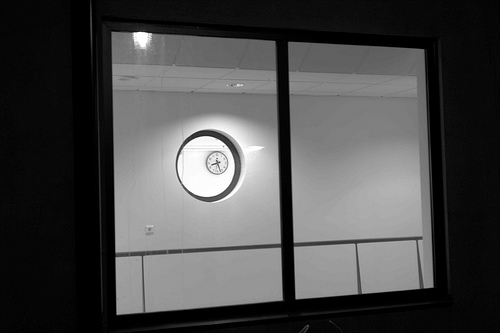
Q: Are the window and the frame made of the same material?
A: No, the window is made of glass and the frame is made of metal.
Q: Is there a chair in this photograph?
A: No, there are no chairs.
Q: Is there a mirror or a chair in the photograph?
A: No, there are no chairs or mirrors.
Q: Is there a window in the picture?
A: Yes, there is a window.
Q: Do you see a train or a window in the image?
A: Yes, there is a window.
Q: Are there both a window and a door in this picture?
A: No, there is a window but no doors.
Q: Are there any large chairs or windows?
A: Yes, there is a large window.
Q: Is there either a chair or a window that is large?
A: Yes, the window is large.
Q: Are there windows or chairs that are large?
A: Yes, the window is large.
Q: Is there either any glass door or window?
A: Yes, there is a glass window.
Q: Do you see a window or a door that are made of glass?
A: Yes, the window is made of glass.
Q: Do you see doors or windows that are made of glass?
A: Yes, the window is made of glass.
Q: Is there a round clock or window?
A: Yes, there is a round window.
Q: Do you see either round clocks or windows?
A: Yes, there is a round window.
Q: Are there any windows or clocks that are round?
A: Yes, the window is round.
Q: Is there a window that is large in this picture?
A: Yes, there is a large window.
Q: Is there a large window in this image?
A: Yes, there is a large window.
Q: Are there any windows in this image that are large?
A: Yes, there is a window that is large.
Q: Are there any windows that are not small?
A: Yes, there is a large window.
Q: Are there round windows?
A: Yes, there is a round window.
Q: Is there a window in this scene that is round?
A: Yes, there is a window that is round.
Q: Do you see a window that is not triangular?
A: Yes, there is a round window.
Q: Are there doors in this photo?
A: No, there are no doors.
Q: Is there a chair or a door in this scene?
A: No, there are no doors or chairs.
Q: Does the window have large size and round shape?
A: Yes, the window is large and round.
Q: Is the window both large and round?
A: Yes, the window is large and round.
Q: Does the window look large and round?
A: Yes, the window is large and round.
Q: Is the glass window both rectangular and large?
A: No, the window is large but round.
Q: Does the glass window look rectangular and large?
A: No, the window is large but round.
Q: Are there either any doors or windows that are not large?
A: No, there is a window but it is large.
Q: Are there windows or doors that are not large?
A: No, there is a window but it is large.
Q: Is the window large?
A: Yes, the window is large.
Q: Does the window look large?
A: Yes, the window is large.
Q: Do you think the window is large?
A: Yes, the window is large.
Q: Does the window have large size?
A: Yes, the window is large.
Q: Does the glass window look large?
A: Yes, the window is large.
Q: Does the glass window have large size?
A: Yes, the window is large.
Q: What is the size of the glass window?
A: The window is large.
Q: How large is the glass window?
A: The window is large.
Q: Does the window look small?
A: No, the window is large.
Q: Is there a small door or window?
A: No, there is a window but it is large.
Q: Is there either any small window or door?
A: No, there is a window but it is large.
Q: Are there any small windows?
A: No, there is a window but it is large.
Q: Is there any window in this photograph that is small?
A: No, there is a window but it is large.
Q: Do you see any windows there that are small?
A: No, there is a window but it is large.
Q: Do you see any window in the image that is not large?
A: No, there is a window but it is large.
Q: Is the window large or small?
A: The window is large.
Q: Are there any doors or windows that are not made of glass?
A: No, there is a window but it is made of glass.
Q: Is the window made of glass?
A: Yes, the window is made of glass.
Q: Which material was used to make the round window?
A: The window is made of glass.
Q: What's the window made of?
A: The window is made of glass.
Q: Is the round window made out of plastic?
A: No, the window is made of glass.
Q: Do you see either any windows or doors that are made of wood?
A: No, there is a window but it is made of glass.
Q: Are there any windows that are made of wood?
A: No, there is a window but it is made of glass.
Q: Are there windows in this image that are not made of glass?
A: No, there is a window but it is made of glass.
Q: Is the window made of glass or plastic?
A: The window is made of glass.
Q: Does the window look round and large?
A: Yes, the window is round and large.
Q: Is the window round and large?
A: Yes, the window is round and large.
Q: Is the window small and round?
A: No, the window is round but large.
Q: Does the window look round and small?
A: No, the window is round but large.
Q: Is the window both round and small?
A: No, the window is round but large.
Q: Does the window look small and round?
A: No, the window is round but large.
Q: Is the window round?
A: Yes, the window is round.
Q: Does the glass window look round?
A: Yes, the window is round.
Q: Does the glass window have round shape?
A: Yes, the window is round.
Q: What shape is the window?
A: The window is round.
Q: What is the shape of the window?
A: The window is round.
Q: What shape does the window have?
A: The window has round shape.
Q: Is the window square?
A: No, the window is round.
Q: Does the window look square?
A: No, the window is round.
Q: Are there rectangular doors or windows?
A: No, there is a window but it is round.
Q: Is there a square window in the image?
A: No, there is a window but it is round.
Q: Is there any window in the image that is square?
A: No, there is a window but it is round.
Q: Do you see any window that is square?
A: No, there is a window but it is round.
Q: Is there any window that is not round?
A: No, there is a window but it is round.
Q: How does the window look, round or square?
A: The window is round.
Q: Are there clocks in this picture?
A: Yes, there is a clock.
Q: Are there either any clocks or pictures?
A: Yes, there is a clock.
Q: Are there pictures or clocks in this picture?
A: Yes, there is a clock.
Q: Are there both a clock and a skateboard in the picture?
A: No, there is a clock but no skateboards.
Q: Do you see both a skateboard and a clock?
A: No, there is a clock but no skateboards.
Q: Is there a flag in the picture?
A: No, there are no flags.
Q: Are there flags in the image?
A: No, there are no flags.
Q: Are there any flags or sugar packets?
A: No, there are no flags or sugar packets.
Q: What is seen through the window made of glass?
A: The clock is seen through the window.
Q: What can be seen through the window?
A: The clock is seen through the window.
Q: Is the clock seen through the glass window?
A: Yes, the clock is seen through the window.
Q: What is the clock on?
A: The clock is on the wall.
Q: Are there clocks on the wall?
A: Yes, there is a clock on the wall.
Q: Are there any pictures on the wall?
A: No, there is a clock on the wall.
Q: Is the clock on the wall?
A: Yes, the clock is on the wall.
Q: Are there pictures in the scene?
A: No, there are no pictures.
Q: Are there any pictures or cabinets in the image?
A: No, there are no pictures or cabinets.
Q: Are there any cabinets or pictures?
A: No, there are no pictures or cabinets.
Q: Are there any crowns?
A: No, there are no crowns.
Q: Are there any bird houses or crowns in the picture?
A: No, there are no crowns or bird houses.